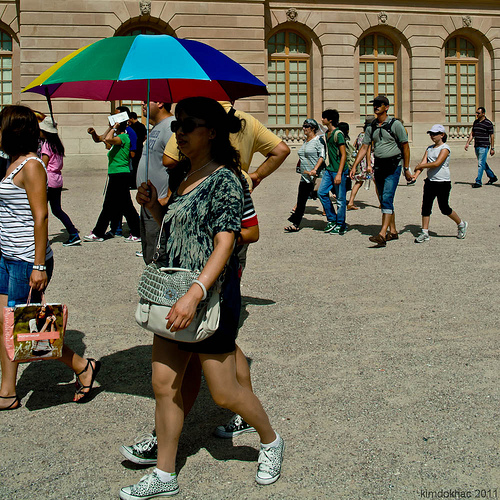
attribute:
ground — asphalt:
[0, 159, 493, 497]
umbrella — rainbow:
[22, 33, 258, 235]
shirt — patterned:
[145, 162, 253, 324]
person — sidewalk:
[411, 118, 471, 245]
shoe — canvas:
[252, 433, 285, 484]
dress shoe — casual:
[70, 355, 100, 405]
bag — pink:
[0, 282, 69, 364]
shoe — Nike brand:
[83, 232, 107, 241]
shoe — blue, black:
[60, 231, 82, 248]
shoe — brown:
[367, 232, 387, 246]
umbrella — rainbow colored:
[15, 32, 271, 206]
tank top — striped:
[0, 155, 54, 265]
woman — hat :
[410, 115, 471, 248]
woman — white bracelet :
[82, 99, 292, 497]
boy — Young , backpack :
[313, 106, 353, 245]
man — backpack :
[312, 101, 358, 234]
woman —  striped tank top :
[4, 90, 95, 411]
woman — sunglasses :
[125, 91, 303, 491]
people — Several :
[15, 85, 481, 473]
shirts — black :
[231, 163, 262, 310]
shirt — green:
[364, 114, 406, 162]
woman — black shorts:
[111, 98, 332, 485]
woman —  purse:
[80, 82, 280, 486]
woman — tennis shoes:
[86, 94, 315, 498]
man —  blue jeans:
[365, 97, 406, 227]